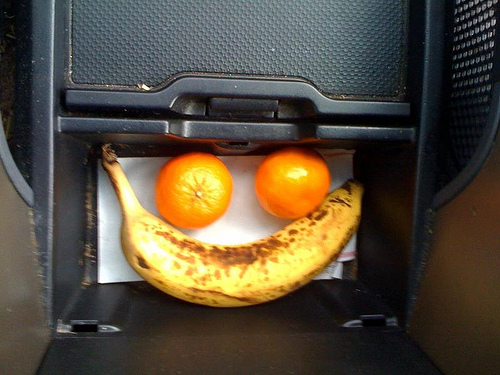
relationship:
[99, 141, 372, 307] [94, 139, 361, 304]
fruits in a smile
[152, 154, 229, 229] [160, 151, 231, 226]
orange has a rind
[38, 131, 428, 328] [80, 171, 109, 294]
bottom has debris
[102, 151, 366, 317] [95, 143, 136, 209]
banana has a stem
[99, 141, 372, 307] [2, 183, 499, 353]
fruits in wall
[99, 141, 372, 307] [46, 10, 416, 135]
fruits in empty compartment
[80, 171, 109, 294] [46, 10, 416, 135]
debris in compartment